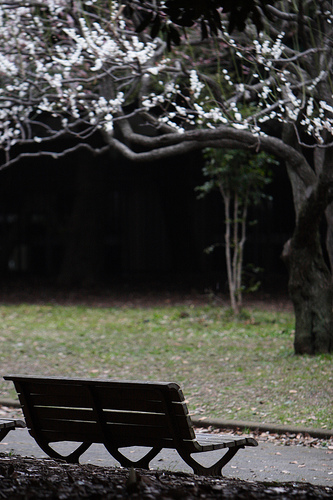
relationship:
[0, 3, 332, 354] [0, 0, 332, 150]
tree has blooms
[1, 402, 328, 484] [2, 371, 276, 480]
path in front of bench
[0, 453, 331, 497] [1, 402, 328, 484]
fallen leaves on path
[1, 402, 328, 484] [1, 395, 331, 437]
path has curb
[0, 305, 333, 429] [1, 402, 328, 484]
grassy area next to path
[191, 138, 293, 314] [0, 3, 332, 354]
tree next to tree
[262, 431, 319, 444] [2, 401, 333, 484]
leaves on pavement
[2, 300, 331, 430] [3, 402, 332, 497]
leaves on pavement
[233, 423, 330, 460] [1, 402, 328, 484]
leaves on path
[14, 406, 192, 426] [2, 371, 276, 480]
slat on bench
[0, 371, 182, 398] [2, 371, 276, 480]
slat on bench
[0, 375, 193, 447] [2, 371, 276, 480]
back of bench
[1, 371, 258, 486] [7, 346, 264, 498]
bench of bench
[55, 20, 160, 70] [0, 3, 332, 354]
flowers on tree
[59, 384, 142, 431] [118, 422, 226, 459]
back of bench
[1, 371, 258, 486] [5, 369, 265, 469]
bench of bench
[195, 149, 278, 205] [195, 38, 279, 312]
leaves of tree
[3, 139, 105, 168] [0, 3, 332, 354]
branch of tree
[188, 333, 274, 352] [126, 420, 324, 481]
leaves at pathway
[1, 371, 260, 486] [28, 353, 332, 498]
bench on sidewalk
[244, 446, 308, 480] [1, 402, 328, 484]
asphalt of path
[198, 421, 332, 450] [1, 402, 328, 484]
leaves on path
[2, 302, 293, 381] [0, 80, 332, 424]
green grass of park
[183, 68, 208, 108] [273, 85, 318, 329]
blossoms on tree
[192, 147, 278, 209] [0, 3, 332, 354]
leaves of tree